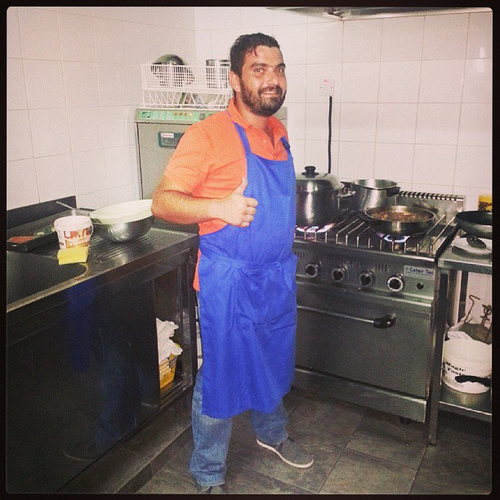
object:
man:
[149, 32, 316, 495]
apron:
[193, 121, 303, 419]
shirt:
[165, 107, 288, 294]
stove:
[294, 167, 464, 435]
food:
[297, 168, 432, 231]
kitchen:
[6, 1, 489, 490]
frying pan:
[366, 206, 436, 228]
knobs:
[381, 272, 405, 295]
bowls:
[148, 57, 198, 89]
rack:
[142, 62, 235, 109]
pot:
[294, 165, 340, 223]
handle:
[297, 302, 397, 330]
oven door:
[297, 290, 435, 403]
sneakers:
[254, 435, 315, 467]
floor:
[133, 381, 418, 496]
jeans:
[188, 291, 292, 483]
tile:
[4, 14, 136, 198]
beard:
[243, 86, 288, 112]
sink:
[7, 210, 200, 308]